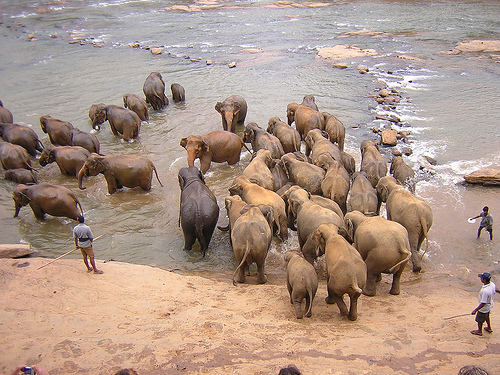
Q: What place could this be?
A: It is a river.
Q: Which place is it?
A: It is a river.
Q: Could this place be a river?
A: Yes, it is a river.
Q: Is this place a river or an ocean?
A: It is a river.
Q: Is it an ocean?
A: No, it is a river.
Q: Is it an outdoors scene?
A: Yes, it is outdoors.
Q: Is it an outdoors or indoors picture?
A: It is outdoors.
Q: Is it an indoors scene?
A: No, it is outdoors.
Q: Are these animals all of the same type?
A: Yes, all the animals are elephants.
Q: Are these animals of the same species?
A: Yes, all the animals are elephants.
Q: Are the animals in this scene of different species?
A: No, all the animals are elephants.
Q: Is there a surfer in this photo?
A: No, there are no surfers.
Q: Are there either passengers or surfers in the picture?
A: No, there are no surfers or passengers.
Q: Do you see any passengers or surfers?
A: No, there are no surfers or passengers.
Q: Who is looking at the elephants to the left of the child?
A: The man is looking at the elephants.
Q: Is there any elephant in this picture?
A: Yes, there is an elephant.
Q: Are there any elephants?
A: Yes, there is an elephant.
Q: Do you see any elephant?
A: Yes, there is an elephant.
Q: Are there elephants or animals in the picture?
A: Yes, there is an elephant.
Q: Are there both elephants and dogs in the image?
A: No, there is an elephant but no dogs.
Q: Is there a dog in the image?
A: No, there are no dogs.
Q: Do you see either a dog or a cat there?
A: No, there are no dogs or cats.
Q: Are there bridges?
A: No, there are no bridges.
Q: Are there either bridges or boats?
A: No, there are no bridges or boats.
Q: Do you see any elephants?
A: Yes, there is an elephant.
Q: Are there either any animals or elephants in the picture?
A: Yes, there is an elephant.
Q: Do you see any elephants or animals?
A: Yes, there is an elephant.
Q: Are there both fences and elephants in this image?
A: No, there is an elephant but no fences.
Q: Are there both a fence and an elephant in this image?
A: No, there is an elephant but no fences.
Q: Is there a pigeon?
A: No, there are no pigeons.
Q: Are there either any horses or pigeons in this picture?
A: No, there are no pigeons or horses.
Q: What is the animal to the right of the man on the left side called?
A: The animal is an elephant.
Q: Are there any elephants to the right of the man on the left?
A: Yes, there is an elephant to the right of the man.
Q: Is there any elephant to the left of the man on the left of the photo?
A: No, the elephant is to the right of the man.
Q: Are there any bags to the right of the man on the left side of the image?
A: No, there is an elephant to the right of the man.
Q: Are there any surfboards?
A: No, there are no surfboards.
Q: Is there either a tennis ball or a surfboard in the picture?
A: No, there are no surfboards or tennis balls.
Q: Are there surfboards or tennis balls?
A: No, there are no surfboards or tennis balls.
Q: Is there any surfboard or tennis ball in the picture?
A: No, there are no surfboards or tennis balls.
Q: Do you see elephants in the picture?
A: Yes, there are elephants.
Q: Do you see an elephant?
A: Yes, there are elephants.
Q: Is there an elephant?
A: Yes, there are elephants.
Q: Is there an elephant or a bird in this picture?
A: Yes, there are elephants.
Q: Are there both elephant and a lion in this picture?
A: No, there are elephants but no lions.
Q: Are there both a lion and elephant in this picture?
A: No, there are elephants but no lions.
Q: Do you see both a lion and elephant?
A: No, there are elephants but no lions.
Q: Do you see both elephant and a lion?
A: No, there are elephants but no lions.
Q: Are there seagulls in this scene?
A: No, there are no seagulls.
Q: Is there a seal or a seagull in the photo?
A: No, there are no seagulls or seals.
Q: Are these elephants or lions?
A: These are elephants.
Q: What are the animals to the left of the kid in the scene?
A: The animals are elephants.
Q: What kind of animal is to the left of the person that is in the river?
A: The animals are elephants.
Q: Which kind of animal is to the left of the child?
A: The animals are elephants.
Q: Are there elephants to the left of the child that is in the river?
A: Yes, there are elephants to the left of the kid.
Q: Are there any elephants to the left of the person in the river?
A: Yes, there are elephants to the left of the kid.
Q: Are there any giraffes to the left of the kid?
A: No, there are elephants to the left of the kid.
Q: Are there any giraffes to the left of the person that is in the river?
A: No, there are elephants to the left of the kid.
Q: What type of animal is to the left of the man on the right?
A: The animals are elephants.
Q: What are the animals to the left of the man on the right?
A: The animals are elephants.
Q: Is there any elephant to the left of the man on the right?
A: Yes, there are elephants to the left of the man.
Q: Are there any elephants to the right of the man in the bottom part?
A: No, the elephants are to the left of the man.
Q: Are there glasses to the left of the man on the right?
A: No, there are elephants to the left of the man.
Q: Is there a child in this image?
A: Yes, there is a child.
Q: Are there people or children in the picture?
A: Yes, there is a child.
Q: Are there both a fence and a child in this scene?
A: No, there is a child but no fences.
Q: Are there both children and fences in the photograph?
A: No, there is a child but no fences.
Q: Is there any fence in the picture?
A: No, there are no fences.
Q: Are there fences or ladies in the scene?
A: No, there are no fences or ladies.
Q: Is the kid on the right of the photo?
A: Yes, the kid is on the right of the image.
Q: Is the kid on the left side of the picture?
A: No, the kid is on the right of the image.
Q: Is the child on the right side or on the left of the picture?
A: The child is on the right of the image.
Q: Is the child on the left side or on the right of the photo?
A: The child is on the right of the image.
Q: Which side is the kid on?
A: The kid is on the right of the image.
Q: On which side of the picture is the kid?
A: The kid is on the right of the image.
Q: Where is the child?
A: The child is in the river.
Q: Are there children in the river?
A: Yes, there is a child in the river.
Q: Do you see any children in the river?
A: Yes, there is a child in the river.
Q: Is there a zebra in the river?
A: No, there is a child in the river.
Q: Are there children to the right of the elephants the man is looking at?
A: Yes, there is a child to the right of the elephants.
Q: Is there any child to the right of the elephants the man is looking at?
A: Yes, there is a child to the right of the elephants.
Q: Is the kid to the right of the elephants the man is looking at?
A: Yes, the kid is to the right of the elephants.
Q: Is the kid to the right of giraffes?
A: No, the kid is to the right of the elephants.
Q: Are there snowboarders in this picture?
A: No, there are no snowboarders.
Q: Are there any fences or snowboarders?
A: No, there are no snowboarders or fences.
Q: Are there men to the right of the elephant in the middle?
A: No, the man is to the left of the elephant.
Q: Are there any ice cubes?
A: No, there are no ice cubes.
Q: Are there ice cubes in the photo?
A: No, there are no ice cubes.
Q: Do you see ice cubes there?
A: No, there are no ice cubes.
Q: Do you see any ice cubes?
A: No, there are no ice cubes.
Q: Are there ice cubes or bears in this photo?
A: No, there are no ice cubes or bears.